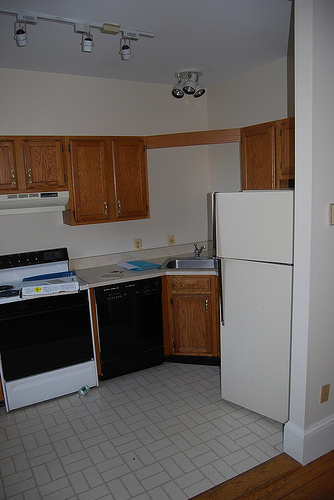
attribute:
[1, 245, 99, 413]
cooker — gas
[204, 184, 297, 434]
refrigerator — white, closed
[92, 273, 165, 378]
dishwasher — black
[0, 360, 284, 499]
tiles — light-colored, white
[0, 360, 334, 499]
floor — tiled, white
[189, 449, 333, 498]
floor — hardwood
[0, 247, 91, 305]
stove — black, white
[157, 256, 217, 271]
sink — silver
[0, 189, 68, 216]
exhaust fan — white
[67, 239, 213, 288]
countertop — beige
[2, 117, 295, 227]
cabinets — wooden, closed, brown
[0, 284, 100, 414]
oven — closed, black, white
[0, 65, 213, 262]
wall — white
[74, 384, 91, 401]
bottle — plastic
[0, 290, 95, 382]
door — black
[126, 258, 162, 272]
book — blue